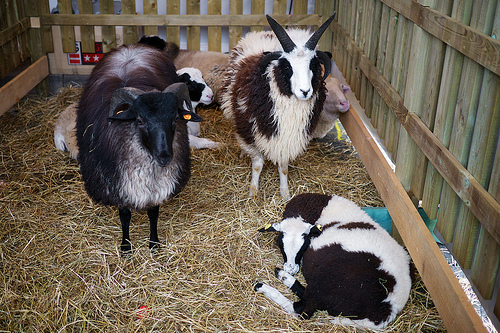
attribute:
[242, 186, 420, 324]
sheep — one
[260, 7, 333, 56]
horns — tall, straight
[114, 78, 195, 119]
horns — curved, black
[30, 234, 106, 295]
hay — fresh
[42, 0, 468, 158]
walls — wooden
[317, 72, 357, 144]
sheep — beige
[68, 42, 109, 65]
sign — red, white, blue, starred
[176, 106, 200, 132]
tag — yellow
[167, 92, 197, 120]
ear — one, sheep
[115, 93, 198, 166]
face — black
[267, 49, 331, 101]
face — black, white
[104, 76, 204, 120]
horns — curved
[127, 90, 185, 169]
face — black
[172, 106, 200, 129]
tag — orange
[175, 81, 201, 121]
ear — one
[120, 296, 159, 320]
object — one, red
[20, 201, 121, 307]
straw — tan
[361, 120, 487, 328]
rail — wooden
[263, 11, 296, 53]
horn — black, pointy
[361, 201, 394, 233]
fabric — blue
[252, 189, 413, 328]
goat — sleeping, brown, white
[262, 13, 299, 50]
horn — large, black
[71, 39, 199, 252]
goat — shaggy, black, brown, white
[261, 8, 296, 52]
horn — large, black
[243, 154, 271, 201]
leg — thin, white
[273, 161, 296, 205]
leg — thin, white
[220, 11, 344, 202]
goat — brown, black, white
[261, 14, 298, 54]
horn — large, points up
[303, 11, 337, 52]
horn — large, black, points up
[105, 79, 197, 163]
head — black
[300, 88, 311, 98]
nose — tiny, black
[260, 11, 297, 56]
horn — large, black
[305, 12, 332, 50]
horn — large, black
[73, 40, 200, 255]
ram — brown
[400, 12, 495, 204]
wall — wooden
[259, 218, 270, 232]
tag — yellow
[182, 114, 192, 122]
tag — orange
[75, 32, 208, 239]
ram — one